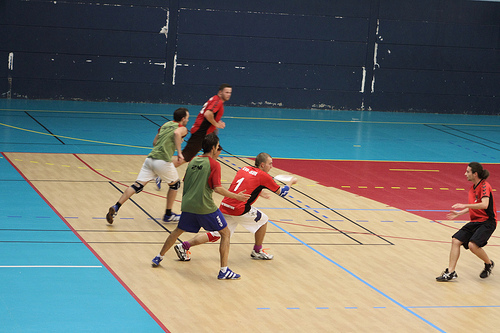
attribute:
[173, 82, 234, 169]
man — grouped, athlete, running, playing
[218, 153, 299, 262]
man — playing, grouped, athlete, throwing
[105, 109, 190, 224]
man — grouped, athlete, playing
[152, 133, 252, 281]
man — playing, grouped, athlete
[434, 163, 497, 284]
man — playing, grouped, athlete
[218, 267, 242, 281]
shoe — blue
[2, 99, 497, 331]
floor — multi-colored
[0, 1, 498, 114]
wall — blue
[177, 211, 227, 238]
shorts — blue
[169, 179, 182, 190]
pad — black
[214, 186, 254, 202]
arm — outstretched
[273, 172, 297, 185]
frisbee — round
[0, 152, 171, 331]
line — red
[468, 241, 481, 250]
knee — bent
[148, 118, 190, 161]
shirt — green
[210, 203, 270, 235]
shorts — white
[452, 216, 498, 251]
shorts — black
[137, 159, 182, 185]
shorts — white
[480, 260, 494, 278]
shoe — black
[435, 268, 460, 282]
shoe — black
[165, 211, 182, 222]
shoe — black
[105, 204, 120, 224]
shoe — black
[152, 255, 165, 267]
shoe — blue